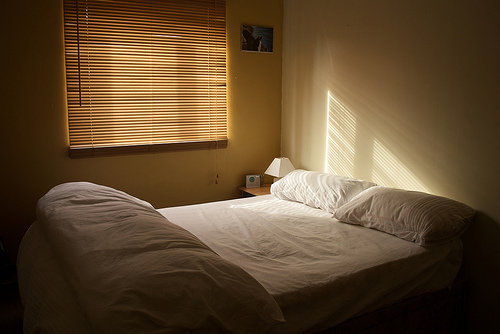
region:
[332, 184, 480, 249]
a white pillow on a bed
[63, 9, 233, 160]
a window near a wall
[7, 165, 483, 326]
a bed near the window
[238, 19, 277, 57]
a drawing on the wall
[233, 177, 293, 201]
a table near a bed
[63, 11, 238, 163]
a window with the shades closed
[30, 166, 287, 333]
a large pillow on the bed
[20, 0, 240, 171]
Wooden blinds on a large window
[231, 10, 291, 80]
Picture on a wall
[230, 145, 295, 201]
Small lamp on a nightstand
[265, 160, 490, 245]
Two large white pillows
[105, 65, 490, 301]
Sunlight shining onto a bed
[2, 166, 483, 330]
White comforter, sheets and pillowcases on bed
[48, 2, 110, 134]
Roll up blind handle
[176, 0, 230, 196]
Roll up blind strings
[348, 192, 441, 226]
a pillow on the bed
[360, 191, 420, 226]
the pillow is white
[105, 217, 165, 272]
a white comforter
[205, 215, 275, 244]
sheets on the bed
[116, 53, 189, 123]
the blinds are brown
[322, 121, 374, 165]
a shadow on the wall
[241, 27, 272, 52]
a picture on the wall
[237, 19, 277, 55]
A rectangular size picture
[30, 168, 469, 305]
a queen size bed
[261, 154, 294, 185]
a small white lamp on the side table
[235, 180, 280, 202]
a wooden night stand beside the bed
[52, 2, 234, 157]
a big window covered by curtain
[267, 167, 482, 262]
two white pillows on top of the bed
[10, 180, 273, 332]
a queen size white comforter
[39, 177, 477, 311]
a bed covered with white sheets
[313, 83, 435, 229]
curtain's shadow on the wall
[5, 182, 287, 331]
a white comforter on the bed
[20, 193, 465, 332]
A bed with white sheets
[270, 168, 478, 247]
Two pillows with white pillow covers on the bed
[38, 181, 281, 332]
Blanket lined with white sheet from inside is rolled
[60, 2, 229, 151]
A window letting in sunlight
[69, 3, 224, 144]
The venetian blinds on the window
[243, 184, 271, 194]
A small noght stand by the bedside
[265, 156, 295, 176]
A white lampshade of a bedside lamp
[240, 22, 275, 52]
A picture frame on the wall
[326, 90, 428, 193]
Sunrays on the wall through the window blinds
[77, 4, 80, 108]
The control stick of the blinds to close them or open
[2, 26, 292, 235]
the wall to the left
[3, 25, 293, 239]
A wall to the left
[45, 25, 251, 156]
The blinds on the window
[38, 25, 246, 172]
A set of blinds on the window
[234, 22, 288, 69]
The picture on the wall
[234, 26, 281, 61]
A picture on the wall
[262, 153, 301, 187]
The white lamp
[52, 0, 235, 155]
Closed the blinds on the window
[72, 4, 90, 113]
A stick to control the blinds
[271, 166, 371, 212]
A white pillow on the bed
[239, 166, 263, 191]
A clock on the bedside table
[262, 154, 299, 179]
A white lampshade on the lamp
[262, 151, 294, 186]
A lamp on the bedside table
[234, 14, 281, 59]
A Small picture on the wall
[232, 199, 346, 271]
White sheets on the bed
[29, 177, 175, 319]
A bedspread pushed to the bottom of the bed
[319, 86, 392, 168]
Shadow of blinds on the wall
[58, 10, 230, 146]
The blinds on the window is closed.